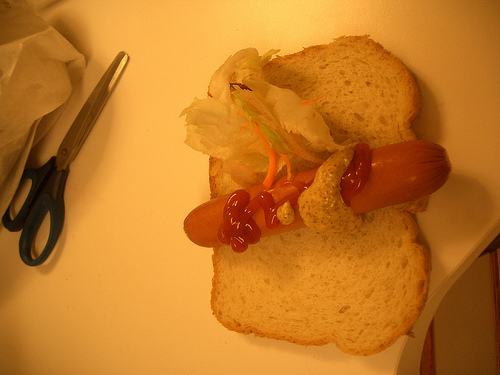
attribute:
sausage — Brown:
[181, 134, 461, 251]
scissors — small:
[2, 44, 133, 269]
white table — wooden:
[2, 1, 498, 373]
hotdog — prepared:
[176, 131, 454, 249]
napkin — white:
[5, 20, 59, 106]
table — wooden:
[0, 2, 498, 372]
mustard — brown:
[286, 154, 357, 248]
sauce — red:
[220, 190, 278, 255]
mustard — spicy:
[278, 144, 363, 237]